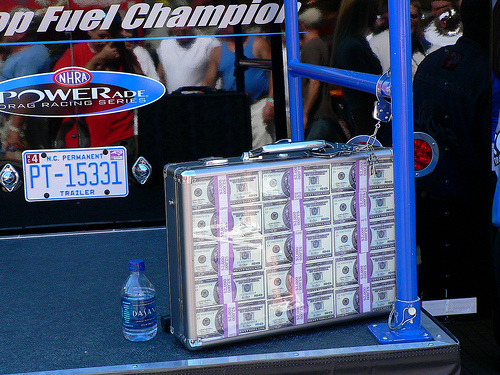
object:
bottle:
[121, 258, 157, 343]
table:
[1, 223, 461, 373]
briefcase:
[164, 139, 407, 351]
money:
[186, 156, 403, 340]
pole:
[383, 0, 419, 340]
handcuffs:
[348, 69, 392, 149]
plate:
[21, 146, 129, 202]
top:
[128, 259, 145, 271]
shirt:
[155, 35, 222, 95]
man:
[155, 14, 223, 94]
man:
[193, 17, 276, 149]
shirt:
[218, 36, 271, 102]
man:
[0, 8, 56, 158]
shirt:
[0, 43, 52, 119]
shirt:
[53, 41, 147, 148]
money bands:
[220, 303, 239, 340]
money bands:
[289, 291, 310, 327]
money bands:
[355, 281, 374, 315]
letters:
[26, 162, 43, 190]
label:
[121, 288, 157, 330]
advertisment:
[0, 66, 166, 122]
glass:
[3, 2, 302, 236]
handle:
[248, 140, 338, 159]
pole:
[284, 0, 305, 144]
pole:
[286, 61, 394, 97]